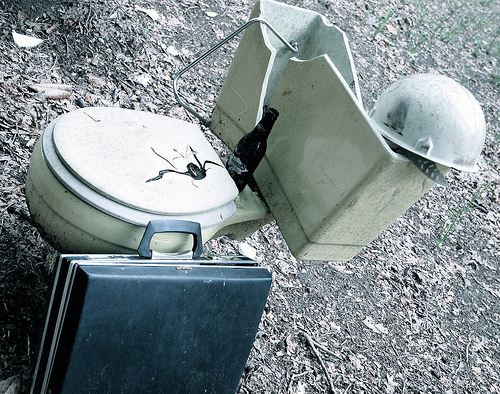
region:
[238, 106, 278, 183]
The bottle is dark in color.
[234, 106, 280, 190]
The bottle is made of glass.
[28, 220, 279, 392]
The brief case is black.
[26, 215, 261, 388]
The brief case is square.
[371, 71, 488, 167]
The helmet is white.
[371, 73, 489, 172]
The helmet is hard.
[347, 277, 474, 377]
The ground is full of leaves.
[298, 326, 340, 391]
The twig is on the ground.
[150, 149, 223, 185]
The toilet has a black stain on it.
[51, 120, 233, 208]
The toilet is white.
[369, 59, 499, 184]
A white hard hat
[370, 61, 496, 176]
A white construction hat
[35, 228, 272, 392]
A black briefcase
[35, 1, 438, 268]
A broken toilet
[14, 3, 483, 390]
A pile of junk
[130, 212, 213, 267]
A black handle sticking up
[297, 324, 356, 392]
A stick on the ground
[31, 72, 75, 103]
A dead leaf on the ground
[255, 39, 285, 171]
A large crack in the toilet tank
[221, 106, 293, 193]
An empty bottle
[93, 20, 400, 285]
broken toilet on the ground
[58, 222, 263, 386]
briefcase on the ground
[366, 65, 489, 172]
hard hat in toilet tank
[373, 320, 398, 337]
leaves on the ground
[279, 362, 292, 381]
leaves on the ground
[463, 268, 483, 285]
leaves on the ground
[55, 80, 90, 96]
leaves on the ground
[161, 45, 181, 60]
leaves on the ground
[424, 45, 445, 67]
leaves on the ground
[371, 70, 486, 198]
a hat on the back of the toilet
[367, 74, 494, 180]
the hat is white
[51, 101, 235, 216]
the lid is closed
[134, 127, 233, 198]
the lid is cracked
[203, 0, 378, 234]
the toilet back is broken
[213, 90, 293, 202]
a bottle on the toilet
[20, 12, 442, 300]
the toilet is dirty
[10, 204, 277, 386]
a briefcase leaning on the toilet bowl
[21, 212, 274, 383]
the briefcase is black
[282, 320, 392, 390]
stick on the ground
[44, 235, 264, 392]
The briefcase is black.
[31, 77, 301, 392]
Briefcase against a toilet.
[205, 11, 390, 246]
The toilet tank is broken.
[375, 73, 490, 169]
Hard hat on the toilet tank.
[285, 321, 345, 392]
Twig on the ground.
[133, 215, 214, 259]
The handle is up.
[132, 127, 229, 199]
Crack in the lid.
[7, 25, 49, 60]
Chunk of the tank on the ground.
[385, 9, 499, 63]
A few blades of grass in the background.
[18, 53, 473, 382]
Leaves cover the ground.